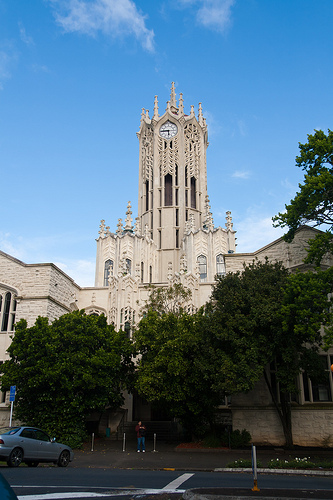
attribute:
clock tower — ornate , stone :
[120, 57, 224, 290]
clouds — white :
[51, 0, 162, 57]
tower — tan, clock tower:
[132, 78, 213, 237]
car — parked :
[0, 423, 72, 467]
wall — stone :
[216, 392, 332, 453]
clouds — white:
[0, 0, 332, 286]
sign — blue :
[7, 384, 16, 403]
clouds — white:
[16, 4, 240, 54]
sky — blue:
[33, 105, 116, 149]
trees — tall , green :
[1, 128, 332, 450]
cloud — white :
[49, 0, 166, 61]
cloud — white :
[169, 1, 241, 39]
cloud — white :
[225, 164, 254, 184]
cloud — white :
[227, 197, 329, 255]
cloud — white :
[2, 221, 98, 286]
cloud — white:
[171, 0, 238, 37]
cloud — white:
[48, 0, 158, 55]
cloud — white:
[236, 210, 315, 255]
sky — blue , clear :
[0, 0, 332, 288]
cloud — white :
[49, 0, 155, 49]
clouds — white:
[27, 1, 249, 80]